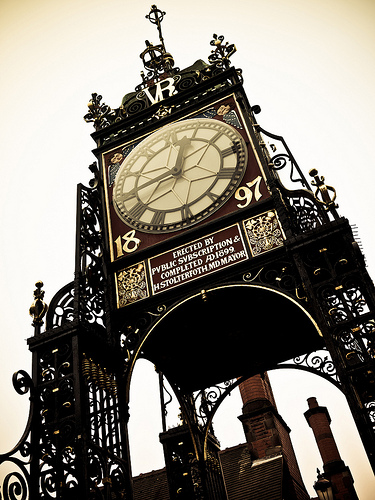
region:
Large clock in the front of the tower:
[105, 113, 263, 232]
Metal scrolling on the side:
[13, 271, 100, 472]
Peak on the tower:
[141, 4, 181, 51]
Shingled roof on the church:
[226, 444, 283, 495]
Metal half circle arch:
[76, 281, 351, 428]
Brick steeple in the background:
[246, 378, 291, 476]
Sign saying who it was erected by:
[114, 223, 283, 303]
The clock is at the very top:
[96, 65, 311, 323]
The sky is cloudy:
[128, 400, 169, 483]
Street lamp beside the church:
[301, 463, 324, 490]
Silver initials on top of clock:
[142, 77, 177, 103]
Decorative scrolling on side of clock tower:
[27, 338, 98, 489]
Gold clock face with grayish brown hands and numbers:
[113, 115, 248, 231]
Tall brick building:
[238, 384, 282, 484]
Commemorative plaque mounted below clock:
[146, 223, 253, 294]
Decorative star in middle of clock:
[137, 141, 219, 203]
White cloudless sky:
[20, 70, 68, 240]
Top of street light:
[315, 466, 331, 499]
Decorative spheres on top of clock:
[138, 2, 167, 73]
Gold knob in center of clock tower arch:
[199, 288, 208, 301]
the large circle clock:
[110, 121, 253, 237]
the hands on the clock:
[118, 132, 197, 205]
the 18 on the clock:
[110, 229, 143, 256]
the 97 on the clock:
[233, 174, 263, 206]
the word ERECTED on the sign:
[170, 241, 203, 257]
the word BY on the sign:
[200, 234, 212, 244]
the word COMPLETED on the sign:
[157, 256, 202, 271]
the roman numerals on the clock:
[114, 118, 247, 233]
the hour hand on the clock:
[170, 132, 196, 178]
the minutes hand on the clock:
[109, 165, 186, 206]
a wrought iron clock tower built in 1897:
[0, 0, 365, 497]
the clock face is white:
[111, 119, 247, 233]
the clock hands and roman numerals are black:
[114, 121, 244, 232]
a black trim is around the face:
[114, 121, 244, 234]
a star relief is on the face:
[136, 144, 215, 207]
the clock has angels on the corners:
[94, 98, 244, 186]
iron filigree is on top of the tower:
[76, 6, 240, 123]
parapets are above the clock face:
[86, 73, 235, 145]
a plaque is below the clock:
[141, 221, 249, 291]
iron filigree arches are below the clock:
[108, 256, 371, 496]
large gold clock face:
[88, 115, 249, 227]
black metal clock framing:
[20, 339, 126, 490]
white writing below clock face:
[135, 228, 258, 293]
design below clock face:
[233, 206, 289, 252]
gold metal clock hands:
[116, 135, 202, 209]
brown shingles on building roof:
[230, 461, 285, 499]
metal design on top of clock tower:
[93, 2, 207, 74]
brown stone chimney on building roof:
[294, 390, 345, 477]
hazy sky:
[264, 45, 326, 117]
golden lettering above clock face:
[133, 70, 199, 106]